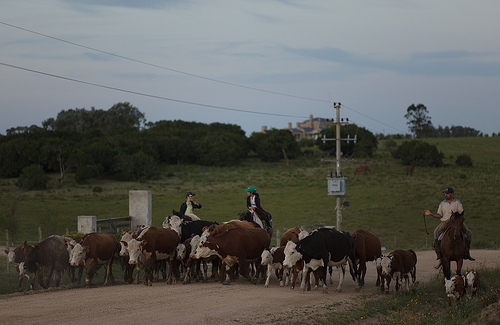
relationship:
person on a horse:
[177, 187, 203, 217] [238, 186, 278, 225]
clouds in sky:
[65, 16, 419, 126] [3, 1, 496, 148]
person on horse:
[244, 181, 269, 231] [189, 214, 282, 283]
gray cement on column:
[129, 188, 157, 228] [125, 190, 154, 231]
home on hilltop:
[260, 114, 348, 141] [1, 139, 481, 200]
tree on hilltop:
[51, 64, 273, 182] [0, 124, 454, 264]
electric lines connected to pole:
[23, 25, 355, 250] [324, 94, 350, 239]